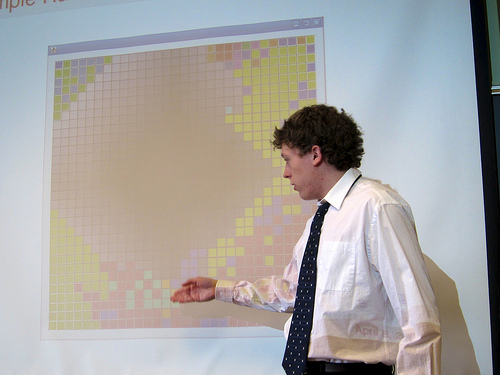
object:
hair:
[268, 105, 365, 167]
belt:
[294, 359, 396, 374]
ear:
[310, 145, 324, 166]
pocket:
[317, 239, 357, 290]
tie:
[282, 197, 333, 374]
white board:
[0, 2, 492, 374]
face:
[277, 148, 311, 202]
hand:
[169, 274, 219, 304]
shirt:
[211, 166, 449, 373]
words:
[315, 236, 390, 356]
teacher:
[167, 94, 452, 372]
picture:
[49, 69, 289, 327]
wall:
[328, 11, 470, 177]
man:
[168, 94, 444, 372]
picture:
[230, 53, 280, 120]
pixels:
[39, 29, 322, 333]